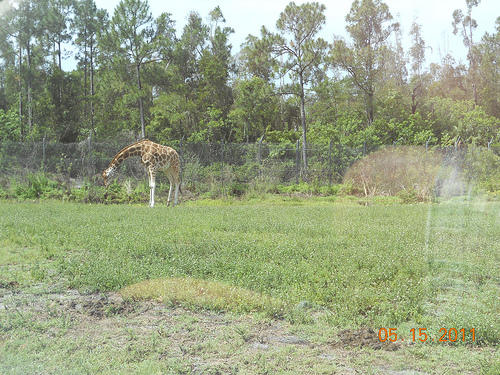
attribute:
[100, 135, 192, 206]
giraffe — bending over, spotted, standing, grazing, tall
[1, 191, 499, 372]
grass — trimmed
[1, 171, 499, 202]
grass — tall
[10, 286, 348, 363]
dirt — bare , patch 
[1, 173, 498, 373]
field — grassy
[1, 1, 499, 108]
sky — clear, blue, light blue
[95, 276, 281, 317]
reflection — present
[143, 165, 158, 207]
front legs — long, white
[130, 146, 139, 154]
spot — brown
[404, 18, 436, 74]
leaves — green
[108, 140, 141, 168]
neck — bent, long, craned down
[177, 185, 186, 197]
hair — black, dark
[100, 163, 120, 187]
head — bent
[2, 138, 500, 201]
fence — wire, metal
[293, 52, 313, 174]
trunk — thin